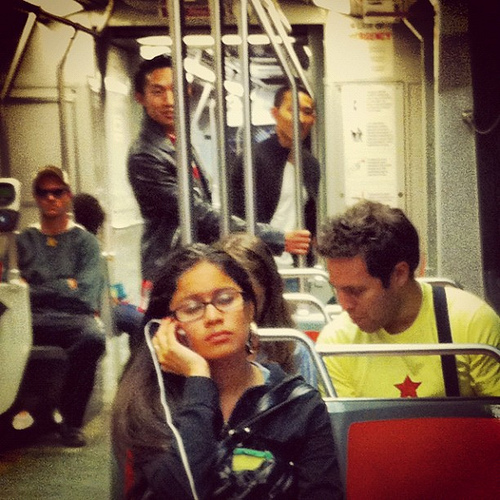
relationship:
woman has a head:
[111, 241, 344, 499] [141, 239, 256, 364]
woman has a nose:
[111, 241, 344, 499] [203, 302, 225, 329]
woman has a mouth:
[111, 241, 344, 499] [205, 329, 235, 346]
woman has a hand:
[111, 241, 344, 499] [148, 315, 211, 376]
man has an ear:
[309, 200, 499, 397] [392, 258, 410, 285]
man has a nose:
[309, 200, 499, 397] [336, 289, 353, 310]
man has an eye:
[309, 200, 499, 397] [347, 287, 364, 299]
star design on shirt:
[395, 376, 422, 399] [310, 279, 499, 400]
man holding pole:
[126, 54, 312, 315] [288, 86, 308, 319]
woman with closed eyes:
[111, 241, 344, 499] [179, 292, 236, 315]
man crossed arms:
[14, 164, 103, 448] [15, 234, 101, 311]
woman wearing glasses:
[111, 241, 344, 499] [168, 289, 254, 321]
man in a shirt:
[309, 200, 499, 397] [310, 279, 499, 400]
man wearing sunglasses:
[14, 164, 103, 448] [37, 184, 64, 199]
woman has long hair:
[111, 241, 344, 499] [108, 239, 260, 464]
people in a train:
[6, 54, 499, 500] [0, 0, 499, 498]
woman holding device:
[111, 241, 344, 499] [174, 329, 191, 347]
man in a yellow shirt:
[309, 200, 499, 397] [310, 279, 499, 400]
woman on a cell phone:
[111, 241, 344, 499] [174, 329, 191, 347]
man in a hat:
[14, 164, 103, 448] [31, 163, 72, 197]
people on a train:
[6, 54, 499, 500] [0, 0, 499, 498]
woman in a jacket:
[111, 241, 344, 499] [134, 364, 343, 499]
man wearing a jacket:
[126, 54, 312, 315] [127, 108, 285, 281]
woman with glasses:
[111, 241, 344, 499] [168, 289, 254, 321]